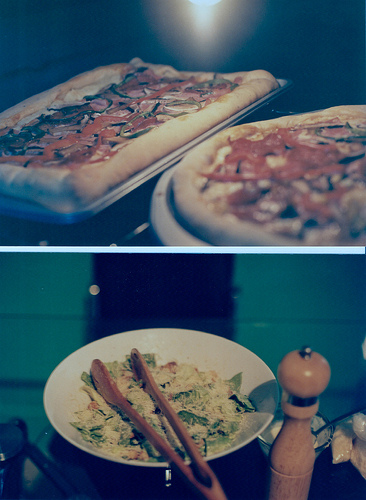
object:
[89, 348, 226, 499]
tongs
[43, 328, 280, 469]
plate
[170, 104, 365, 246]
food